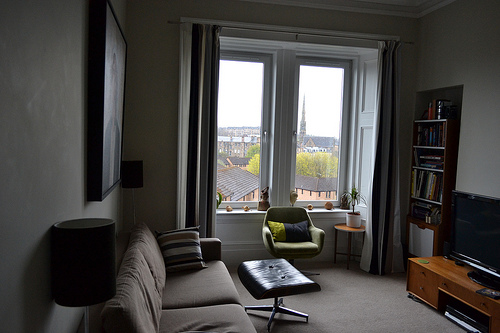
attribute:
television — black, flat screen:
[448, 190, 499, 289]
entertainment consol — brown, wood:
[405, 256, 499, 331]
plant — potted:
[343, 187, 365, 228]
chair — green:
[259, 207, 324, 277]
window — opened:
[218, 51, 351, 207]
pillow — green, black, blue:
[265, 219, 310, 241]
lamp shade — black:
[47, 221, 116, 305]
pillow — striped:
[154, 229, 207, 272]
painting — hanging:
[92, 0, 126, 200]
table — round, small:
[332, 222, 368, 271]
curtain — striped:
[179, 20, 221, 242]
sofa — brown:
[95, 226, 259, 331]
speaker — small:
[439, 241, 451, 261]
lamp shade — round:
[119, 158, 145, 189]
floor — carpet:
[218, 260, 472, 331]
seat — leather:
[233, 256, 322, 322]